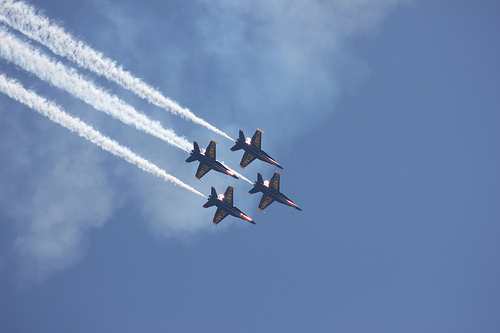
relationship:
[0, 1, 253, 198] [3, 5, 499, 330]
smoke in sky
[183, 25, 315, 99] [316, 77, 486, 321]
clouds in sky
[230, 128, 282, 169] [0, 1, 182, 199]
jet has smoke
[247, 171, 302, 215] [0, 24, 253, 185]
airplanes has smoke trail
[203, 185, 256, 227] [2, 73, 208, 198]
jet has smoke trail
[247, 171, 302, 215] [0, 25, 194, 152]
airplanes has smoke trail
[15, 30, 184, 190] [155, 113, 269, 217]
trails from jets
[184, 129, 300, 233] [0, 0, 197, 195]
airplanes leave tracks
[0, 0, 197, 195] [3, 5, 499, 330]
tracks in sky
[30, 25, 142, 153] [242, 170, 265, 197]
clouds come from tail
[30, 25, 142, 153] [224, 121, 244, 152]
clouds come from tail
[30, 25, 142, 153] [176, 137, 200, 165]
clouds come from tail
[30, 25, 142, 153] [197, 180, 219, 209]
clouds come from tail